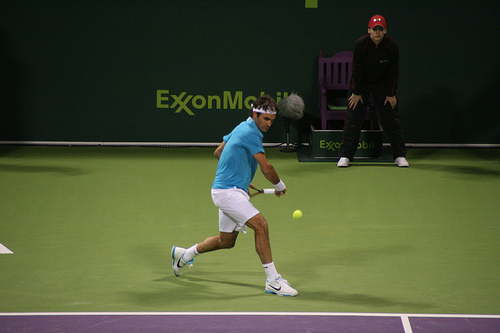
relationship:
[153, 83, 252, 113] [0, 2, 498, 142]
logo in background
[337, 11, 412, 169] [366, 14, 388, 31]
man in cap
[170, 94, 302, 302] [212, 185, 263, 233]
players wears shorts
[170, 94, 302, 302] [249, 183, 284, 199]
player playing racket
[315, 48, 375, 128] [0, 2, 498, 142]
chair against wall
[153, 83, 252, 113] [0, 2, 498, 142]
logo on wall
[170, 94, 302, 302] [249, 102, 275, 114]
man wearing headband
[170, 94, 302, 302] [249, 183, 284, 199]
man playing racket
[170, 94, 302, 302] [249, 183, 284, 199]
male playing racket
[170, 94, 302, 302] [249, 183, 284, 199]
adult playing racket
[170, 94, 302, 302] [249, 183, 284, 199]
person playing racket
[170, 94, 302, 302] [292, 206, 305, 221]
person striking ball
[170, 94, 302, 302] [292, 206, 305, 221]
male striking ball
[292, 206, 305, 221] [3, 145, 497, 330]
ball on court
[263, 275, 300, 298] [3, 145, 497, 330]
foot on court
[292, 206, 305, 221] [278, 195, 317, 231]
ball in air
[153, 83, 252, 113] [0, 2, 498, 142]
logo on background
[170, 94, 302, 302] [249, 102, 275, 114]
man wearing sweatband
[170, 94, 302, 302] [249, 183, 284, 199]
man holding racket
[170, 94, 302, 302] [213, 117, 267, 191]
man wearing shirt